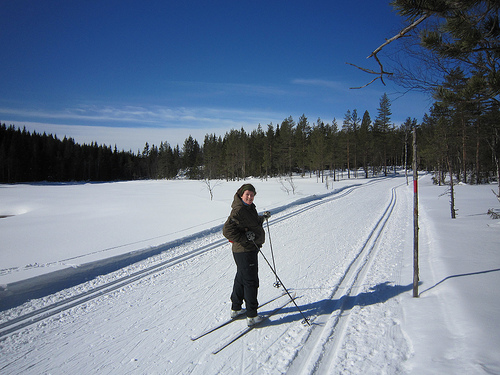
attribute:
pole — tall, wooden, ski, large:
[408, 122, 425, 299]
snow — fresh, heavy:
[1, 175, 497, 373]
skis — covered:
[190, 286, 299, 356]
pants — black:
[226, 245, 268, 319]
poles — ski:
[244, 226, 312, 329]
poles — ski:
[263, 211, 282, 292]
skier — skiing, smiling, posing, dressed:
[217, 181, 279, 328]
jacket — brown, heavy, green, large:
[222, 192, 267, 258]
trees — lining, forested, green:
[134, 107, 447, 178]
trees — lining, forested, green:
[1, 119, 178, 187]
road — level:
[1, 162, 430, 373]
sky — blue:
[1, 1, 498, 157]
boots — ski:
[244, 311, 267, 327]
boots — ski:
[229, 306, 247, 321]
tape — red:
[411, 175, 420, 192]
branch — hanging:
[340, 10, 437, 99]